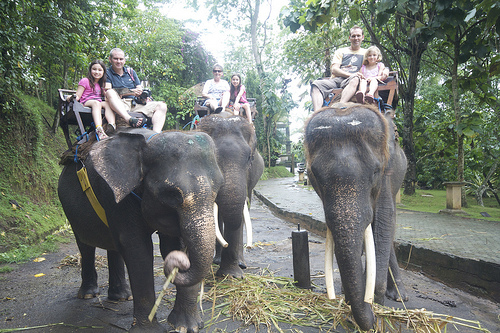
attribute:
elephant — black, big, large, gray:
[303, 104, 415, 327]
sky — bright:
[144, 0, 312, 145]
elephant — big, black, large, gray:
[57, 127, 224, 329]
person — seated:
[91, 44, 170, 123]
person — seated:
[94, 35, 175, 122]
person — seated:
[192, 63, 257, 133]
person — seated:
[205, 58, 260, 122]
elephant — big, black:
[192, 90, 292, 233]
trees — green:
[369, 2, 497, 179]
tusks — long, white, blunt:
[339, 229, 404, 295]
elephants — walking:
[77, 103, 449, 327]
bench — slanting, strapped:
[47, 99, 120, 221]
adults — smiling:
[100, 41, 149, 127]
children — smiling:
[219, 66, 407, 97]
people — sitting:
[65, 30, 447, 118]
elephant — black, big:
[294, 101, 395, 331]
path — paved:
[38, 191, 484, 330]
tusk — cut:
[323, 226, 337, 303]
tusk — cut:
[362, 225, 378, 308]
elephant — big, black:
[306, 108, 409, 321]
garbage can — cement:
[443, 181, 466, 213]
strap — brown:
[75, 168, 107, 231]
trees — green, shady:
[11, 2, 201, 254]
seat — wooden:
[54, 85, 124, 142]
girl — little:
[361, 40, 389, 100]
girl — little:
[231, 71, 254, 125]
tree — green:
[354, 6, 482, 202]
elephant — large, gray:
[187, 111, 267, 278]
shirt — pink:
[72, 74, 102, 106]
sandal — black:
[119, 111, 150, 128]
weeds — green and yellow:
[200, 261, 494, 329]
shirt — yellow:
[331, 43, 366, 78]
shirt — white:
[200, 76, 232, 108]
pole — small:
[287, 223, 313, 291]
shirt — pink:
[355, 60, 392, 84]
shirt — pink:
[77, 76, 102, 106]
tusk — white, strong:
[363, 220, 378, 305]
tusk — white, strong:
[322, 216, 336, 299]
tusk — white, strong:
[241, 197, 256, 253]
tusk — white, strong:
[211, 200, 230, 250]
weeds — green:
[172, 227, 349, 330]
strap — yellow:
[60, 153, 114, 232]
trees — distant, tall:
[289, 19, 499, 223]